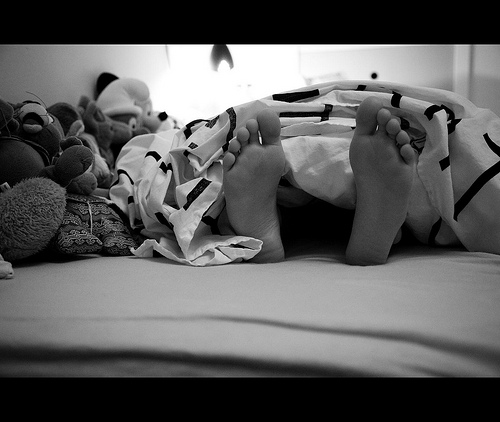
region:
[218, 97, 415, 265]
Feet under the blanket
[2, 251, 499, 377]
Sheets on the bed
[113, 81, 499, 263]
A blanket on the person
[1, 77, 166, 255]
Stuffed animals on the bed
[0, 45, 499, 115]
The wall near the bed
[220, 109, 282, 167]
Toes on the foot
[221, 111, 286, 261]
The right foot of the person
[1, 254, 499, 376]
A bed below the person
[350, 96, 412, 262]
The left foot of the person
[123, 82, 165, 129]
A Mickey Mouse stuffed animal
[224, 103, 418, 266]
a persons feet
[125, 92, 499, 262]
a persons feet sticking out from under a blanket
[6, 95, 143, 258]
teddy bears on the bed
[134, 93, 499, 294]
a white blanket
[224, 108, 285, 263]
a foot on the bed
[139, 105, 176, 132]
the face of a teddy bear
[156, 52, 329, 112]
a light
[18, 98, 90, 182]
a stuffed animal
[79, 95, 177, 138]
the faces of the animals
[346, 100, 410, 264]
a person's left foot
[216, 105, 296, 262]
a person's right foot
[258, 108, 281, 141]
big toe on right foot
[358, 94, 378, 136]
the big toe on left foot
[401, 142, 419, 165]
pinky toe on left foot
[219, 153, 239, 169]
pinky toe on right foot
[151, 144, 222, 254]
sheet on the bed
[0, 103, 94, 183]
brown teddy bear on bed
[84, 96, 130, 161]
stuffed animal on bed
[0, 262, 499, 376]
the bed in the room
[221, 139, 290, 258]
a persons foot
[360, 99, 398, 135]
toes on the foot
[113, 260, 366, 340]
bed sheets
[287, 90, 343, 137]
a blanket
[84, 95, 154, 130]
stuffed animals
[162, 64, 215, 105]
a bright light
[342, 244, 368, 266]
heel of the foot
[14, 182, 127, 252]
items on the bed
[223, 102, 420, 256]
two feet on the bed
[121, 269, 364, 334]
a bed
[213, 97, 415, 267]
The feet have ten toes.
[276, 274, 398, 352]
The bed has a wrinkle.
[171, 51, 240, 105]
The sun is shining through the window.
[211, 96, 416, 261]
The feet are bare.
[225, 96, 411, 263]
The feet are small.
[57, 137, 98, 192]
The stuff animal is dark in color.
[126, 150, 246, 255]
The bed sheet is white and black.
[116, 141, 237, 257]
The white sheet has black stripes.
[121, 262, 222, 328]
The bed sheet is light in color.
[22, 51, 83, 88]
The wall is light in color.